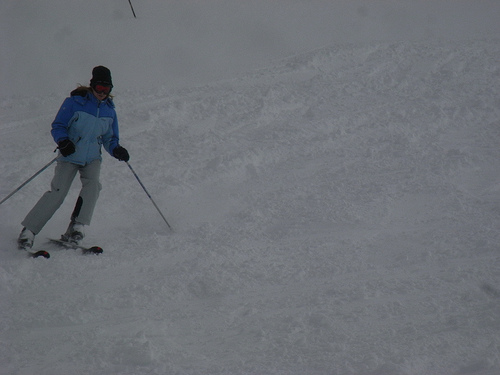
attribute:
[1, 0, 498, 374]
snow — background, white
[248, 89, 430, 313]
snow — white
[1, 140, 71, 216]
pole — ski pole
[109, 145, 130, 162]
glove — black 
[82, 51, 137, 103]
head — lady's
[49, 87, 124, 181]
jacket — blue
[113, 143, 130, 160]
glove — black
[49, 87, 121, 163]
jacket —  blue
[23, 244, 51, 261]
ski equipment — skiing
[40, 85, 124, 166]
jacket — blue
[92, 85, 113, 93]
goggles — snow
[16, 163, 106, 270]
snow pants — white 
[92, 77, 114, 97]
goggles — red 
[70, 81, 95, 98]
hood — black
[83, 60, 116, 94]
hat — black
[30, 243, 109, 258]
top — black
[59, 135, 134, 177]
hands —  lady's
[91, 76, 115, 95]
face — lady's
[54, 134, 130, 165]
hand — woman's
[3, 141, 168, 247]
gear — skiing